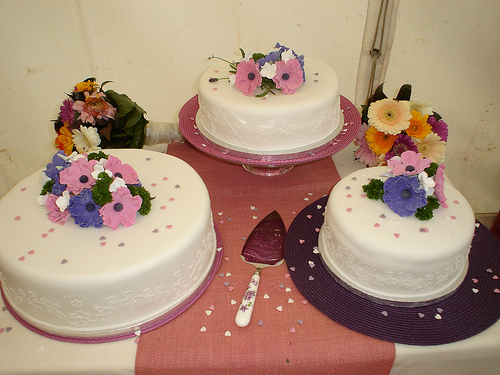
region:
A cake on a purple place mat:
[283, 151, 497, 336]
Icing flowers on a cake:
[364, 152, 442, 221]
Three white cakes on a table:
[9, 46, 463, 348]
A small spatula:
[226, 206, 286, 327]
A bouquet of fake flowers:
[46, 80, 146, 147]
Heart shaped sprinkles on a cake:
[12, 227, 82, 272]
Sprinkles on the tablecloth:
[256, 277, 316, 345]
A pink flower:
[232, 55, 260, 98]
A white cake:
[321, 153, 481, 295]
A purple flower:
[66, 190, 106, 226]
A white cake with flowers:
[12, 147, 217, 350]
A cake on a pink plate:
[178, 49, 344, 176]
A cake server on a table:
[238, 204, 284, 340]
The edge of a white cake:
[37, 265, 145, 303]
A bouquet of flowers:
[37, 69, 166, 150]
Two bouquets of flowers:
[33, 71, 460, 162]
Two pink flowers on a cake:
[230, 58, 317, 97]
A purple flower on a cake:
[382, 167, 432, 228]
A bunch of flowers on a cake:
[35, 151, 171, 268]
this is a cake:
[1, 183, 205, 310]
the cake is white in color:
[1, 182, 202, 314]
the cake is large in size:
[0, 155, 204, 318]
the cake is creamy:
[1, 163, 216, 330]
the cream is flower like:
[47, 146, 151, 232]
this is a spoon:
[230, 215, 282, 325]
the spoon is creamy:
[239, 216, 286, 265]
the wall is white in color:
[2, 4, 348, 37]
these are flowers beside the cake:
[56, 97, 134, 134]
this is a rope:
[358, 2, 393, 80]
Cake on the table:
[0, 165, 260, 335]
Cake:
[333, 183, 415, 371]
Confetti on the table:
[91, 162, 315, 327]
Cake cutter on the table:
[227, 201, 294, 373]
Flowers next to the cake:
[358, 93, 498, 222]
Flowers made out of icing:
[21, 142, 168, 241]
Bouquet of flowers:
[48, 86, 187, 153]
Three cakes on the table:
[33, 77, 468, 309]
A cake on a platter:
[148, 33, 363, 191]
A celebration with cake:
[61, 48, 489, 371]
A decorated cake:
[180, 30, 349, 160]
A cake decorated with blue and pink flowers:
[13, 145, 203, 335]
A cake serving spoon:
[229, 207, 291, 342]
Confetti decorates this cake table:
[248, 202, 258, 221]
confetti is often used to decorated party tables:
[246, 202, 261, 222]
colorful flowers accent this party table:
[365, 85, 434, 159]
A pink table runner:
[144, 342, 251, 373]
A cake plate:
[296, 219, 326, 300]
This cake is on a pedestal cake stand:
[180, 46, 351, 189]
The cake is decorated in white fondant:
[16, 167, 177, 315]